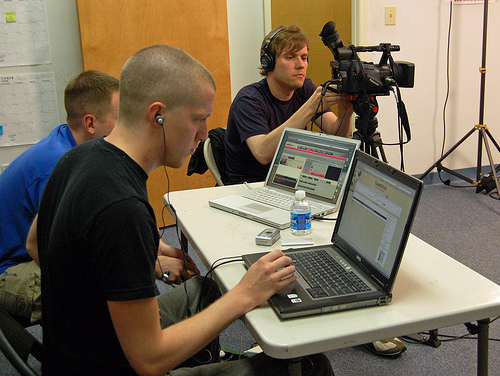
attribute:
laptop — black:
[240, 151, 423, 322]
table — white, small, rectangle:
[163, 182, 499, 374]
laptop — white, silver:
[209, 127, 364, 232]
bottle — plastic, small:
[288, 189, 313, 246]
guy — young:
[24, 46, 333, 375]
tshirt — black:
[36, 135, 161, 375]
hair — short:
[115, 45, 218, 132]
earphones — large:
[154, 110, 245, 366]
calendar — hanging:
[1, 69, 63, 151]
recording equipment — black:
[310, 19, 417, 171]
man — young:
[2, 71, 120, 324]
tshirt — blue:
[1, 123, 75, 275]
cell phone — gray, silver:
[254, 222, 282, 246]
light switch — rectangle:
[386, 4, 398, 26]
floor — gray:
[2, 175, 499, 376]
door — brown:
[74, 3, 231, 229]